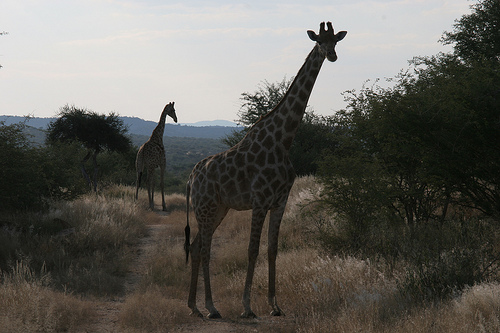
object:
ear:
[307, 30, 319, 41]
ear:
[335, 30, 347, 41]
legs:
[243, 203, 268, 306]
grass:
[8, 226, 111, 325]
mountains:
[0, 114, 224, 165]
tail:
[182, 176, 191, 265]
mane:
[254, 46, 315, 127]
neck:
[283, 49, 326, 121]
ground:
[72, 225, 314, 331]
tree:
[43, 102, 137, 193]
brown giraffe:
[135, 101, 178, 212]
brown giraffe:
[182, 21, 347, 319]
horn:
[319, 20, 327, 30]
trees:
[296, 77, 459, 250]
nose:
[328, 50, 336, 55]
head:
[307, 21, 347, 62]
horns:
[326, 21, 334, 32]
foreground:
[313, 212, 463, 323]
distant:
[11, 42, 200, 183]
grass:
[290, 239, 442, 331]